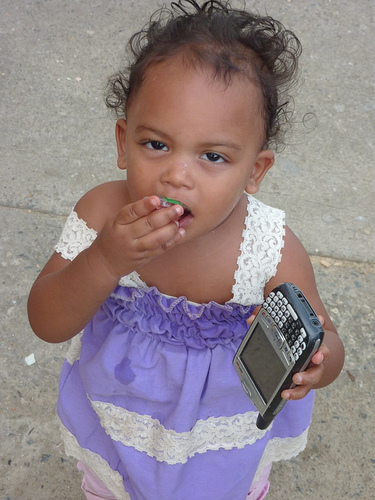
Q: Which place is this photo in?
A: It is at the sidewalk.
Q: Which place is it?
A: It is a sidewalk.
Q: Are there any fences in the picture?
A: No, there are no fences.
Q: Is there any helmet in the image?
A: No, there are no helmets.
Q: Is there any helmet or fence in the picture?
A: No, there are no helmets or fences.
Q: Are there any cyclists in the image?
A: No, there are no cyclists.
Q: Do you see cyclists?
A: No, there are no cyclists.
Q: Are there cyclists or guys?
A: No, there are no cyclists or guys.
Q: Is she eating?
A: Yes, the girl is eating.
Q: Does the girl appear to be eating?
A: Yes, the girl is eating.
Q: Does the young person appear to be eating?
A: Yes, the girl is eating.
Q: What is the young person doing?
A: The girl is eating.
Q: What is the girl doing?
A: The girl is eating.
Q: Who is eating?
A: The girl is eating.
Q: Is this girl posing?
A: No, the girl is eating.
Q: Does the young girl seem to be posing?
A: No, the girl is eating.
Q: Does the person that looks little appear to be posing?
A: No, the girl is eating.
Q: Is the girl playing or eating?
A: The girl is eating.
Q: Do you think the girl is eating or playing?
A: The girl is eating.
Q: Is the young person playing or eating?
A: The girl is eating.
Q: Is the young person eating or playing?
A: The girl is eating.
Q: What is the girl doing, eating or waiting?
A: The girl is eating.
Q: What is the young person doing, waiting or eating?
A: The girl is eating.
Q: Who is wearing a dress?
A: The girl is wearing a dress.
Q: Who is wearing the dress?
A: The girl is wearing a dress.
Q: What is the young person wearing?
A: The girl is wearing a dress.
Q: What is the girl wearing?
A: The girl is wearing a dress.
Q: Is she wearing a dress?
A: Yes, the girl is wearing a dress.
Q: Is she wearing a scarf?
A: No, the girl is wearing a dress.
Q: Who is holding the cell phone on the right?
A: The girl is holding the cellphone.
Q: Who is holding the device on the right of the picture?
A: The girl is holding the cellphone.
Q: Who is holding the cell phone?
A: The girl is holding the cellphone.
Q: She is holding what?
A: The girl is holding the cell phone.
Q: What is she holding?
A: The girl is holding the cell phone.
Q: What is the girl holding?
A: The girl is holding the cell phone.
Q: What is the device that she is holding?
A: The device is a cell phone.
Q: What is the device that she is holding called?
A: The device is a cell phone.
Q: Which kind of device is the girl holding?
A: The girl is holding the cell phone.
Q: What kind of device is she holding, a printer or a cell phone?
A: The girl is holding a cell phone.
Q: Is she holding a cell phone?
A: Yes, the girl is holding a cell phone.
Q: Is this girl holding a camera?
A: No, the girl is holding a cell phone.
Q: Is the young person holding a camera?
A: No, the girl is holding a cell phone.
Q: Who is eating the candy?
A: The girl is eating the candy.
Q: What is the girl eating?
A: The girl is eating a candy.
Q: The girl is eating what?
A: The girl is eating a candy.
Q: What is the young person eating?
A: The girl is eating a candy.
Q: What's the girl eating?
A: The girl is eating a candy.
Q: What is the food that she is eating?
A: The food is a candy.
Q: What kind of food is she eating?
A: The girl is eating a candy.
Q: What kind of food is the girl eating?
A: The girl is eating a candy.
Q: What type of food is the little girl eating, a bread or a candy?
A: The girl is eating a candy.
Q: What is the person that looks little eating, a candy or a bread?
A: The girl is eating a candy.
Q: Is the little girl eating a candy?
A: Yes, the girl is eating a candy.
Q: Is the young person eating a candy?
A: Yes, the girl is eating a candy.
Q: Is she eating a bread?
A: No, the girl is eating a candy.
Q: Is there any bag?
A: No, there are no bags.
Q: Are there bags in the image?
A: No, there are no bags.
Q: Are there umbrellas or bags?
A: No, there are no bags or umbrellas.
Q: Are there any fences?
A: No, there are no fences.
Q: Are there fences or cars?
A: No, there are no fences or cars.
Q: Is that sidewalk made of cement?
A: Yes, the sidewalk is made of cement.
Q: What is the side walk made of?
A: The side walk is made of cement.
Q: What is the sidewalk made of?
A: The side walk is made of concrete.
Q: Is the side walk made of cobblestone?
A: No, the side walk is made of concrete.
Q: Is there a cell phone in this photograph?
A: Yes, there is a cell phone.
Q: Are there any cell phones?
A: Yes, there is a cell phone.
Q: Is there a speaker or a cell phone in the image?
A: Yes, there is a cell phone.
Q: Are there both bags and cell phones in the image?
A: No, there is a cell phone but no bags.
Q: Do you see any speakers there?
A: No, there are no speakers.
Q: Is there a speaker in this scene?
A: No, there are no speakers.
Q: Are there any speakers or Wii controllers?
A: No, there are no speakers or Wii controllers.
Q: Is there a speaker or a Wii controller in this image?
A: No, there are no speakers or Wii controllers.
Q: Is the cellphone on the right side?
A: Yes, the cellphone is on the right of the image.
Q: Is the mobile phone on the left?
A: No, the mobile phone is on the right of the image.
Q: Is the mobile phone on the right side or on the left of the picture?
A: The mobile phone is on the right of the image.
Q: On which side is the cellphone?
A: The cellphone is on the right of the image.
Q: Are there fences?
A: No, there are no fences.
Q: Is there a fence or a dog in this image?
A: No, there are no fences or dogs.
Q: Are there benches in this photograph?
A: No, there are no benches.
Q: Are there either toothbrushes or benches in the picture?
A: No, there are no benches or toothbrushes.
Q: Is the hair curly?
A: Yes, the hair is curly.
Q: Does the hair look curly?
A: Yes, the hair is curly.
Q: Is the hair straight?
A: No, the hair is curly.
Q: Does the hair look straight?
A: No, the hair is curly.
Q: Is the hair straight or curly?
A: The hair is curly.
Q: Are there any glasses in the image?
A: No, there are no glasses.